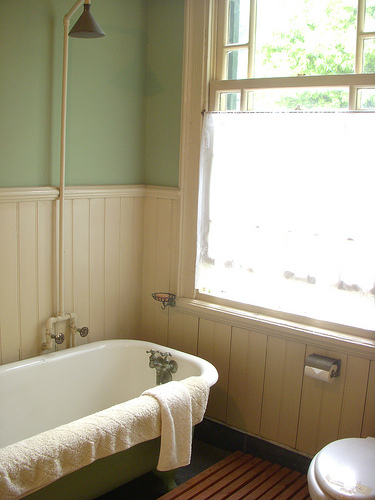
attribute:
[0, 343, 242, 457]
tub — white, green, wooden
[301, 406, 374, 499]
toilet — white, closed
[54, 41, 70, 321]
pipeline — white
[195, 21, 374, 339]
window — white, large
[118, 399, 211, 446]
towels — white, hanging, draped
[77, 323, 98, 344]
wrench — grey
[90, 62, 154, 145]
wall — green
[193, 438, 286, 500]
mat — brown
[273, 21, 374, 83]
leaves — green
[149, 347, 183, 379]
faucets — old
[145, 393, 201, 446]
towel — white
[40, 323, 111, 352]
handles — hot, cold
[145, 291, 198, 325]
dish — old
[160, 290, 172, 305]
soap — pink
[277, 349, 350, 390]
paper — white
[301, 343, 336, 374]
paper roll — silver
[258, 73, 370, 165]
sunshine — shining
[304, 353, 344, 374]
holder — mounted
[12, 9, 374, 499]
bathroom — clean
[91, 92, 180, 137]
walls — green